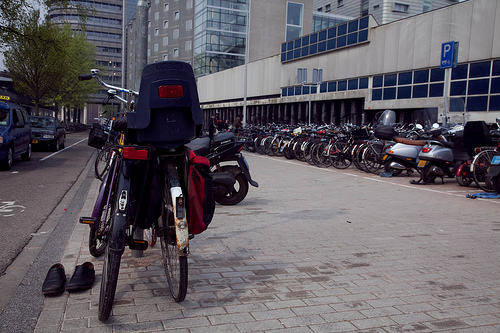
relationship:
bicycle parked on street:
[77, 133, 143, 316] [22, 121, 493, 332]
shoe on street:
[46, 256, 65, 296] [171, 139, 497, 331]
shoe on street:
[69, 263, 94, 295] [171, 139, 497, 331]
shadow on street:
[118, 237, 288, 309] [83, 93, 490, 331]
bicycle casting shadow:
[38, 115, 262, 312] [221, 216, 299, 313]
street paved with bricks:
[22, 121, 493, 332] [28, 103, 495, 330]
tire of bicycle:
[98, 223, 123, 320] [81, 69, 148, 321]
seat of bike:
[123, 57, 205, 154] [110, 59, 237, 306]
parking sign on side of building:
[440, 41, 457, 68] [196, 3, 496, 214]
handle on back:
[77, 62, 148, 143] [95, 63, 230, 284]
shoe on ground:
[65, 261, 96, 291] [0, 132, 499, 330]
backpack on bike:
[128, 59, 203, 149] [54, 46, 259, 322]